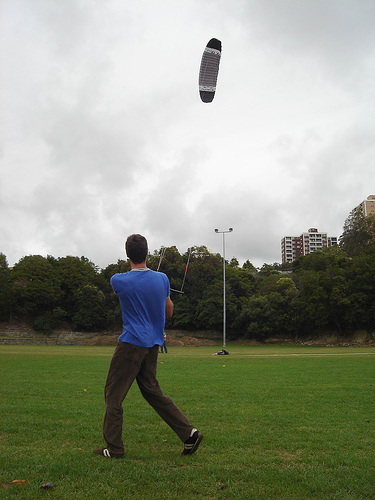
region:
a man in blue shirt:
[71, 209, 245, 437]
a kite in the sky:
[187, 30, 228, 112]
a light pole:
[205, 220, 234, 354]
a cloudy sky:
[1, 2, 372, 268]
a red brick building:
[343, 192, 373, 241]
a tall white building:
[280, 225, 338, 263]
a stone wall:
[3, 321, 96, 347]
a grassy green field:
[0, 343, 374, 497]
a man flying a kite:
[90, 234, 210, 461]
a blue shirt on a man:
[107, 268, 178, 353]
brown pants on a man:
[100, 333, 193, 461]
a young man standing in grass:
[88, 230, 209, 465]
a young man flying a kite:
[90, 33, 235, 459]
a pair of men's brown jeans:
[93, 334, 194, 453]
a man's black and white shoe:
[180, 428, 200, 455]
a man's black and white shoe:
[87, 441, 123, 457]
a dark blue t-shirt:
[109, 266, 166, 348]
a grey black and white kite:
[195, 33, 222, 106]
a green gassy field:
[0, 340, 370, 498]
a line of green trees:
[0, 236, 372, 347]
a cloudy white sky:
[0, 0, 369, 264]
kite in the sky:
[194, 40, 238, 110]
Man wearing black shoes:
[182, 429, 203, 459]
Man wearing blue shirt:
[106, 275, 171, 346]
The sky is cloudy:
[222, 174, 291, 216]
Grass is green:
[259, 382, 352, 462]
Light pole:
[212, 214, 240, 353]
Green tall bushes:
[297, 267, 364, 312]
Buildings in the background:
[276, 227, 335, 258]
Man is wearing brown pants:
[117, 347, 162, 389]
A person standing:
[161, 330, 173, 350]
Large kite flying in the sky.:
[188, 87, 228, 103]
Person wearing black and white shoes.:
[95, 435, 199, 461]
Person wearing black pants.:
[105, 385, 182, 440]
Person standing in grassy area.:
[79, 442, 254, 488]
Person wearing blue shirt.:
[102, 289, 165, 363]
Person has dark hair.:
[119, 229, 174, 298]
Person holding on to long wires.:
[146, 251, 208, 344]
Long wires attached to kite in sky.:
[160, 228, 224, 335]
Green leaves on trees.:
[243, 276, 314, 319]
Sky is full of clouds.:
[70, 96, 251, 197]